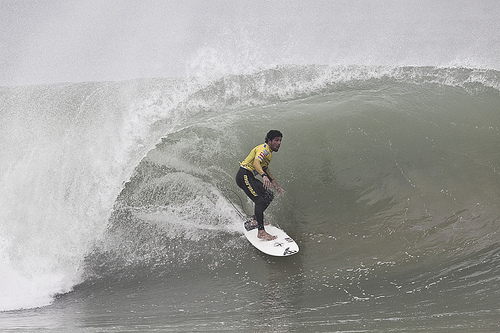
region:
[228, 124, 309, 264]
man on a surf board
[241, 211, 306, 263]
white surf board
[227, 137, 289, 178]
tight yellow shirt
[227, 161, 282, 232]
tight black pants with yellow writing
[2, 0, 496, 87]
hazy grey over cast sky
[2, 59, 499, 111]
edge of an ocean wave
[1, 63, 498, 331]
grey and white coloured water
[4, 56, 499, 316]
large ocean wave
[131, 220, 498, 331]
white foam floating in grey water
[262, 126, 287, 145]
short black curly hair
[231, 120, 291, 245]
a surfer on a surfboard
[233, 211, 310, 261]
surfboard is white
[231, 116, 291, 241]
surfboard wears a yellow shirt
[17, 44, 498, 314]
surfer is in the center of a wave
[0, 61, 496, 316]
big wave is rolling in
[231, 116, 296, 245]
man wears a wet suit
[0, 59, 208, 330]
part of wave that is crushing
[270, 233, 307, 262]
nose of surfboard has decorations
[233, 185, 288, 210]
knees of man are bend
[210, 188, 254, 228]
a string on tail of surfboard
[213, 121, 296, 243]
the man on the surfboard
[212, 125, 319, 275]
the man is surfing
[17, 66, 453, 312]
the wave in the ocean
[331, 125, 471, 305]
the ocean is opaque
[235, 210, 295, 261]
the surfboard is white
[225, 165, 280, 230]
the man wearing black pants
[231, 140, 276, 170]
the man wearing a yellow shirt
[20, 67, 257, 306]
the wave is large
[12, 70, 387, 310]
the wave is rolling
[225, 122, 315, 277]
the man on the water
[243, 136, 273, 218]
black and yellow rashguard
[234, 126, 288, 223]
black and yellow rashguard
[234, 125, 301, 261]
a man surfing in the ocean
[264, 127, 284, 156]
the surker has dark hair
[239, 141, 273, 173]
a yellow top is on the man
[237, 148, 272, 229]
the surfer is wearing a body suit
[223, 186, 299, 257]
the surfer is tethered to the board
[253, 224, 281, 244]
the surfer is barefoot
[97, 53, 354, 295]
the surfe is in the curl of the wave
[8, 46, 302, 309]
the wave is crashing behind him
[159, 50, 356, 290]
the surfer has caught a beautiful ride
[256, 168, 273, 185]
the man has a black watch